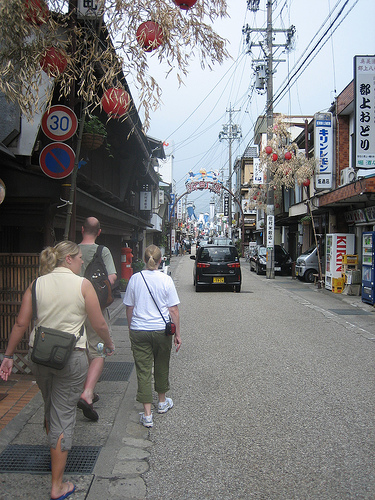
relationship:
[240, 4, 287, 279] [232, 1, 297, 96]
pole of power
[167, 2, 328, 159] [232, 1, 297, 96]
cables of power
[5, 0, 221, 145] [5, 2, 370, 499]
tree in picture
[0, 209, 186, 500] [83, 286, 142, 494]
people walking down  street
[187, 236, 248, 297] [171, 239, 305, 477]
car driving down street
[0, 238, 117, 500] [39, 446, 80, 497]
people wearing flip flops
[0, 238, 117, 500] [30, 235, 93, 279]
people has blonde hai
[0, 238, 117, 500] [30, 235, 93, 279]
people wearing ponytail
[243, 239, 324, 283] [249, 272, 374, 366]
cars parked on sidewalk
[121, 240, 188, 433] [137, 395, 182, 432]
woman wearing sneakers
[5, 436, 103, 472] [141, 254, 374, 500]
storm drain on down street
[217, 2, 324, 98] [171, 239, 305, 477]
power lines above street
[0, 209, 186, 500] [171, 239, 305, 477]
people walking down street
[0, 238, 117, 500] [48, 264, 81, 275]
people wearing collared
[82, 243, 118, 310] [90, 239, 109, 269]
backpack slung from shoulder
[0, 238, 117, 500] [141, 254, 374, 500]
people looking down street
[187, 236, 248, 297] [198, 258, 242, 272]
car has taillights